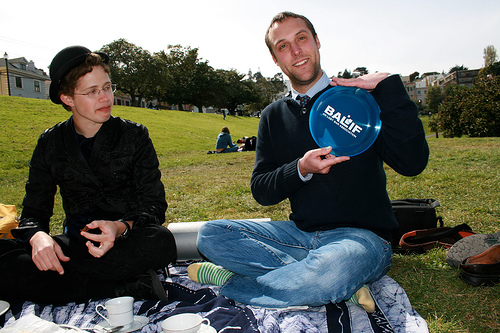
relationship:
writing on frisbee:
[322, 104, 363, 137] [309, 86, 381, 162]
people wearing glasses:
[2, 45, 183, 307] [70, 81, 120, 101]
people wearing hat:
[2, 45, 183, 307] [49, 44, 112, 100]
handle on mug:
[93, 303, 106, 323] [95, 295, 135, 333]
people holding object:
[2, 45, 183, 307] [79, 225, 87, 232]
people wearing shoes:
[2, 45, 183, 307] [110, 268, 167, 301]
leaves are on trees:
[101, 40, 284, 110] [107, 35, 284, 114]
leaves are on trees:
[431, 76, 499, 136] [428, 68, 499, 139]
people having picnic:
[2, 45, 183, 307] [0, 293, 415, 332]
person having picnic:
[189, 4, 430, 310] [0, 293, 415, 332]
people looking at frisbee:
[2, 45, 183, 307] [309, 86, 381, 162]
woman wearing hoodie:
[215, 126, 237, 152] [215, 132, 234, 148]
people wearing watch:
[2, 45, 183, 307] [117, 219, 130, 240]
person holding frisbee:
[189, 4, 430, 310] [309, 86, 381, 162]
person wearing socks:
[189, 4, 430, 310] [189, 261, 376, 310]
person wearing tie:
[189, 4, 430, 310] [298, 93, 309, 112]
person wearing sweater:
[189, 4, 430, 310] [248, 74, 428, 239]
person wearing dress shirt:
[189, 4, 430, 310] [289, 75, 331, 108]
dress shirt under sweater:
[289, 75, 331, 108] [248, 74, 428, 239]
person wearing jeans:
[189, 4, 430, 310] [198, 216, 393, 304]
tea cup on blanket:
[95, 295, 135, 333] [0, 275, 416, 332]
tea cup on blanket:
[160, 314, 213, 330] [0, 275, 416, 332]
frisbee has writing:
[309, 86, 381, 162] [322, 104, 363, 137]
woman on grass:
[215, 126, 240, 154] [4, 96, 495, 329]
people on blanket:
[2, 9, 432, 309] [0, 275, 416, 332]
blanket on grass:
[0, 275, 416, 332] [4, 96, 495, 329]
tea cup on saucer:
[160, 314, 213, 330] [162, 324, 221, 332]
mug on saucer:
[95, 295, 135, 333] [93, 313, 149, 332]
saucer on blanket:
[162, 324, 221, 332] [0, 275, 416, 332]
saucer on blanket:
[93, 313, 149, 332] [0, 275, 416, 332]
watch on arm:
[117, 219, 130, 240] [95, 125, 168, 261]